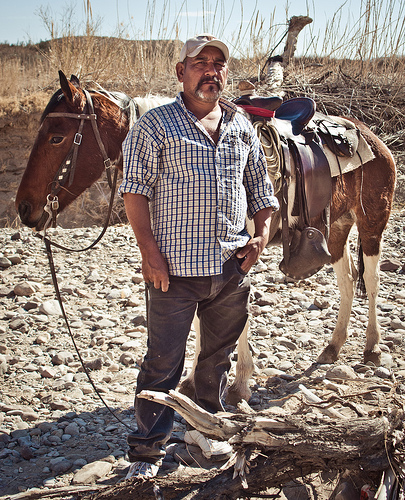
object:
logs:
[0, 389, 405, 500]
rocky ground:
[0, 212, 404, 496]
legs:
[355, 199, 391, 343]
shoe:
[124, 458, 160, 479]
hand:
[235, 236, 264, 273]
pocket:
[227, 257, 251, 294]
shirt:
[117, 92, 279, 279]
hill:
[0, 34, 207, 80]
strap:
[43, 239, 158, 434]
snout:
[16, 191, 35, 225]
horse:
[14, 70, 396, 405]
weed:
[0, 0, 405, 122]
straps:
[33, 151, 120, 252]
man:
[118, 36, 280, 483]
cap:
[180, 33, 230, 63]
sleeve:
[117, 127, 161, 201]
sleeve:
[244, 141, 280, 217]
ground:
[0, 209, 405, 500]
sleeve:
[244, 137, 280, 220]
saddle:
[274, 98, 328, 278]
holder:
[280, 227, 333, 280]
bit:
[44, 194, 59, 232]